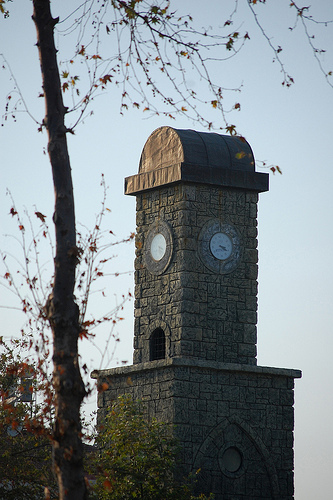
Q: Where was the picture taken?
A: By a clock tower.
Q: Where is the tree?
A: To the left of the tower.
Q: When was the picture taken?
A: In Autumn.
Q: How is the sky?
A: Clear.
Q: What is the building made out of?
A: Stone bricks.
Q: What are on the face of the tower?
A: Clocks.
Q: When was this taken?
A: 3:21.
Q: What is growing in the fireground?
A: Tree.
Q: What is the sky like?
A: Clear.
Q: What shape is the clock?
A: Round.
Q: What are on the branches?
A: Leaves.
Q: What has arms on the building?
A: Clock.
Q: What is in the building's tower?
A: A clock.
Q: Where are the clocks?
A: On the tower.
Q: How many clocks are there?
A: 2.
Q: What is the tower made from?
A: Stone.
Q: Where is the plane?
A: There isn't one.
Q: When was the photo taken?
A: Daytime.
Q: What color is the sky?
A: Pale blue.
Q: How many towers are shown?
A: 1.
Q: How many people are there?
A: None.